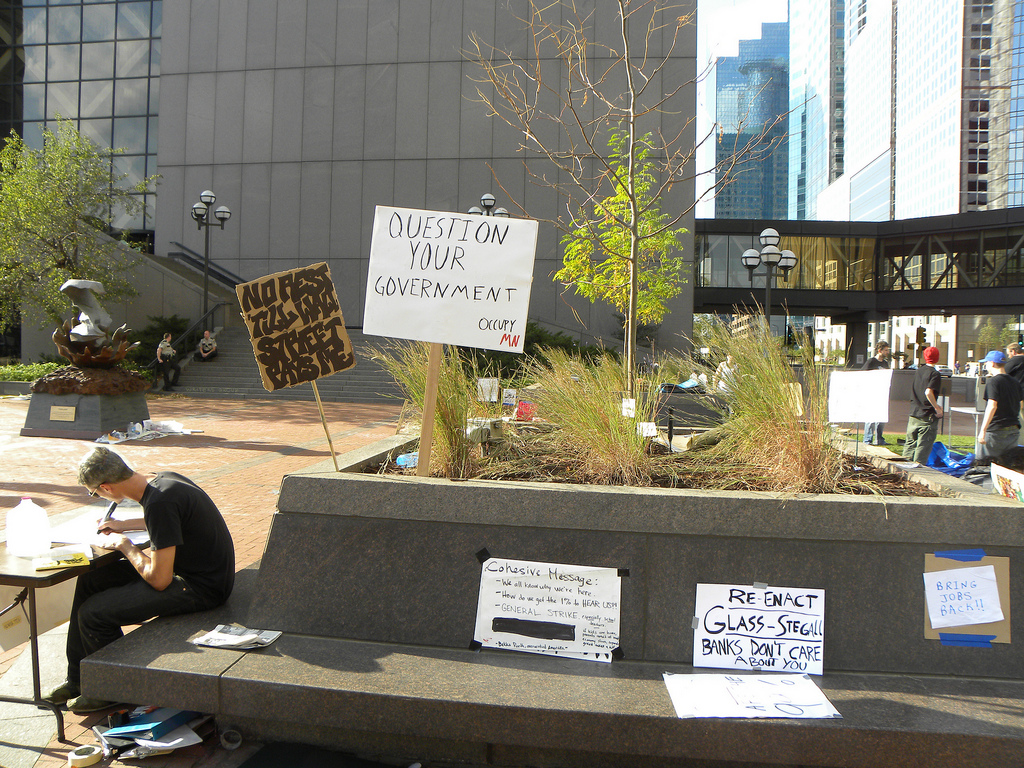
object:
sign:
[362, 205, 539, 355]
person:
[38, 446, 233, 712]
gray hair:
[77, 446, 133, 484]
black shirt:
[139, 471, 234, 605]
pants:
[66, 560, 210, 686]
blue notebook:
[102, 708, 192, 742]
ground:
[0, 393, 427, 767]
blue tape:
[935, 548, 987, 562]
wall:
[247, 473, 1023, 680]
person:
[976, 351, 1023, 464]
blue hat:
[979, 350, 1008, 364]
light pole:
[203, 208, 210, 334]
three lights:
[191, 190, 231, 230]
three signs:
[463, 554, 1010, 676]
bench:
[79, 557, 1020, 768]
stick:
[416, 336, 441, 478]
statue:
[30, 279, 151, 395]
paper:
[923, 565, 1004, 630]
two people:
[902, 347, 1024, 466]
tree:
[453, 0, 818, 400]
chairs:
[926, 442, 975, 479]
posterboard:
[363, 204, 539, 478]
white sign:
[693, 584, 826, 676]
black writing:
[693, 583, 825, 675]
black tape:
[475, 547, 491, 564]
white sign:
[474, 557, 622, 663]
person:
[902, 347, 944, 467]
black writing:
[236, 261, 356, 392]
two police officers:
[157, 330, 218, 391]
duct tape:
[69, 745, 103, 763]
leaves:
[552, 239, 594, 281]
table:
[0, 504, 151, 742]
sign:
[662, 671, 843, 718]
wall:
[154, 0, 695, 360]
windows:
[22, 0, 162, 232]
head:
[923, 346, 940, 364]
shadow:
[150, 567, 394, 672]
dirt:
[358, 421, 939, 498]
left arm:
[95, 499, 177, 591]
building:
[0, 0, 696, 406]